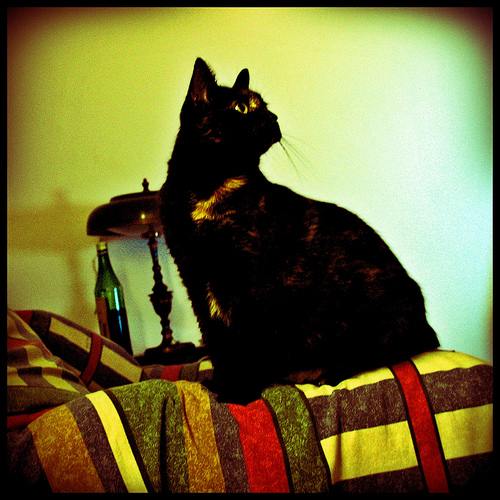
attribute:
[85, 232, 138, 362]
glass bottle — tall, green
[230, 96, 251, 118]
eye — pretty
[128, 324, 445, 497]
stripes — big, brown, white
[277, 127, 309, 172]
whiskers — black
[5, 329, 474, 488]
stripes — big, brown, white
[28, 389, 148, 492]
stripes — white, big, brown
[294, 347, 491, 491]
stripes — white, big, brown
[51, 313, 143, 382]
stripes — white, big, brown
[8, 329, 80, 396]
stripes — white, big, brown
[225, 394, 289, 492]
stripes — brown, big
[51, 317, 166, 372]
diagonal stripe — white, black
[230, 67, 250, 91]
ear — furry, black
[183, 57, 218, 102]
ear — furry, black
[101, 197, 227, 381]
lamp base — cast iron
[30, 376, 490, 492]
blanket — chenille, multicolored, striped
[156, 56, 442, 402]
cat — yellow